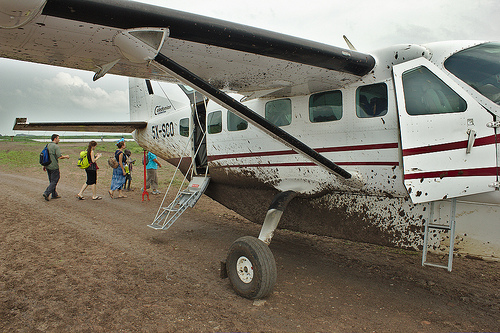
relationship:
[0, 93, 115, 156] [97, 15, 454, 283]
fin of airplane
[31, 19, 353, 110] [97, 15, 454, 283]
wing of airplane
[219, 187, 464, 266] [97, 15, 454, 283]
bottom of plane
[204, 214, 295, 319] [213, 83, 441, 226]
wheel on plane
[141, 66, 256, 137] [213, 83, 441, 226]
back of plane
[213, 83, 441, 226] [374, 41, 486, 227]
plane has door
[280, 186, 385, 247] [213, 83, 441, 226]
mud on plane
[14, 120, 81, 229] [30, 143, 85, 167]
man has shirt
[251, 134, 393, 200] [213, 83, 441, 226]
line on plane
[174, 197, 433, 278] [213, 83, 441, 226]
side of plane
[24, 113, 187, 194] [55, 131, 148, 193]
group of tourist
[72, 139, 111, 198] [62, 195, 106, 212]
woman has feet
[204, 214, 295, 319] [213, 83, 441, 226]
wheel of plane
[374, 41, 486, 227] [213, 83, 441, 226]
door of plane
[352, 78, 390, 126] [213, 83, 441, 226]
window on plane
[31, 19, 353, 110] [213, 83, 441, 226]
wing of plane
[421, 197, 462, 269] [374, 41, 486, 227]
ladder hanging from door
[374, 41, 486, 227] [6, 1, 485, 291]
door of plane